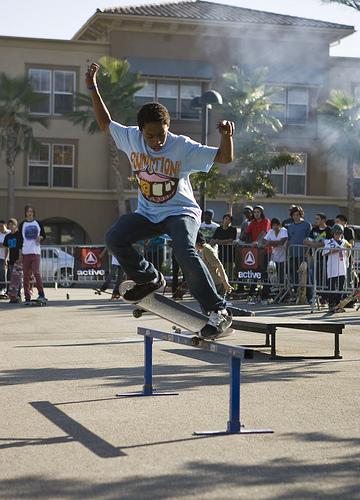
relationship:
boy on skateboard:
[86, 60, 238, 342] [120, 279, 233, 339]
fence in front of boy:
[224, 240, 359, 306] [323, 224, 353, 304]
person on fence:
[266, 218, 289, 289] [224, 240, 359, 306]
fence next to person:
[224, 240, 359, 306] [266, 218, 289, 289]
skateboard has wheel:
[120, 279, 233, 339] [131, 309, 145, 321]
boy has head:
[86, 60, 238, 342] [136, 97, 172, 152]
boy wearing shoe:
[86, 60, 238, 342] [200, 307, 234, 340]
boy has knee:
[86, 60, 238, 342] [101, 230, 132, 255]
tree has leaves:
[1, 70, 48, 216] [13, 110, 52, 131]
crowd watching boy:
[202, 203, 355, 299] [86, 60, 238, 342]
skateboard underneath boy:
[120, 279, 233, 339] [86, 60, 238, 342]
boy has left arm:
[86, 60, 238, 342] [187, 118, 236, 168]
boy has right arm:
[86, 60, 238, 342] [86, 61, 138, 143]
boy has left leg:
[86, 60, 238, 342] [168, 217, 229, 310]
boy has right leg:
[86, 60, 238, 342] [107, 213, 159, 281]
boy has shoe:
[86, 60, 238, 342] [200, 307, 234, 340]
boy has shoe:
[86, 60, 238, 342] [125, 272, 168, 302]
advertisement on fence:
[74, 246, 109, 275] [224, 240, 359, 306]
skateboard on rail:
[120, 279, 233, 339] [135, 324, 254, 360]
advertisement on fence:
[70, 242, 113, 286] [7, 239, 134, 288]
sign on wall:
[228, 240, 266, 281] [209, 238, 359, 293]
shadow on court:
[31, 395, 210, 458] [5, 306, 359, 495]